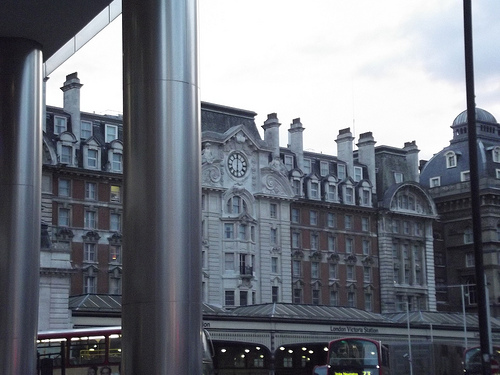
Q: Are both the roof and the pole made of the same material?
A: Yes, both the roof and the pole are made of metal.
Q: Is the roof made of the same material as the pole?
A: Yes, both the roof and the pole are made of metal.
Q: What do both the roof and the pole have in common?
A: The material, both the roof and the pole are metallic.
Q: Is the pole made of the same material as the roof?
A: Yes, both the pole and the roof are made of metal.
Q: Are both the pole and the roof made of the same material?
A: Yes, both the pole and the roof are made of metal.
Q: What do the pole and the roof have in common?
A: The material, both the pole and the roof are metallic.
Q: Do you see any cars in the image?
A: No, there are no cars.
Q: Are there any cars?
A: No, there are no cars.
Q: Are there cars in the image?
A: No, there are no cars.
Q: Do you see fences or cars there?
A: No, there are no cars or fences.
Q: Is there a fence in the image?
A: No, there are no fences.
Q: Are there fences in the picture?
A: No, there are no fences.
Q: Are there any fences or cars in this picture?
A: No, there are no fences or cars.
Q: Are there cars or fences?
A: No, there are no fences or cars.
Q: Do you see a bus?
A: Yes, there is a bus.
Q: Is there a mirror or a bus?
A: Yes, there is a bus.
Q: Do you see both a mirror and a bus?
A: Yes, there are both a bus and a mirror.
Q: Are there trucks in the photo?
A: No, there are no trucks.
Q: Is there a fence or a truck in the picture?
A: No, there are no trucks or fences.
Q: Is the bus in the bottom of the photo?
A: Yes, the bus is in the bottom of the image.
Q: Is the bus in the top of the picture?
A: No, the bus is in the bottom of the image.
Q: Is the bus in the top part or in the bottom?
A: The bus is in the bottom of the image.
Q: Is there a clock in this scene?
A: Yes, there is a clock.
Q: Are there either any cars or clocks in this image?
A: Yes, there is a clock.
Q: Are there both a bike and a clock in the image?
A: No, there is a clock but no bikes.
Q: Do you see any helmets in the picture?
A: No, there are no helmets.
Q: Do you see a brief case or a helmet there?
A: No, there are no helmets or briefcases.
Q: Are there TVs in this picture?
A: No, there are no tvs.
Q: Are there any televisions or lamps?
A: No, there are no televisions or lamps.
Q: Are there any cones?
A: No, there are no cones.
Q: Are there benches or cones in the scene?
A: No, there are no cones or benches.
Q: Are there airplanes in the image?
A: No, there are no airplanes.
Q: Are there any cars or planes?
A: No, there are no planes or cars.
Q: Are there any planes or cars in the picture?
A: No, there are no planes or cars.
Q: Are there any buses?
A: Yes, there is a bus.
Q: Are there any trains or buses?
A: Yes, there is a bus.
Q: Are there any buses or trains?
A: Yes, there is a bus.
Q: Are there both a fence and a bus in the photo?
A: No, there is a bus but no fences.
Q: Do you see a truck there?
A: No, there are no trucks.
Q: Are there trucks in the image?
A: No, there are no trucks.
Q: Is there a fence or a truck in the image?
A: No, there are no trucks or fences.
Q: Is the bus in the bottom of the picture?
A: Yes, the bus is in the bottom of the image.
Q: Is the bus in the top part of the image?
A: No, the bus is in the bottom of the image.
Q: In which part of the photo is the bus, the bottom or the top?
A: The bus is in the bottom of the image.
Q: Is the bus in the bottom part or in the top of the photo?
A: The bus is in the bottom of the image.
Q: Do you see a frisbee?
A: No, there are no frisbees.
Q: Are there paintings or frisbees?
A: No, there are no frisbees or paintings.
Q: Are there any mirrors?
A: Yes, there is a mirror.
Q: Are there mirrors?
A: Yes, there is a mirror.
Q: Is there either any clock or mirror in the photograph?
A: Yes, there is a mirror.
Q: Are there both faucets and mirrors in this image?
A: No, there is a mirror but no faucets.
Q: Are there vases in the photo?
A: No, there are no vases.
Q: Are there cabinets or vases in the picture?
A: No, there are no vases or cabinets.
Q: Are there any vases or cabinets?
A: No, there are no vases or cabinets.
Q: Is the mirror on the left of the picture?
A: Yes, the mirror is on the left of the image.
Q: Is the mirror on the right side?
A: No, the mirror is on the left of the image.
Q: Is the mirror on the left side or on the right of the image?
A: The mirror is on the left of the image.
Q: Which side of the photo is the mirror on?
A: The mirror is on the left of the image.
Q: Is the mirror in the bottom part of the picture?
A: Yes, the mirror is in the bottom of the image.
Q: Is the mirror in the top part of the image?
A: No, the mirror is in the bottom of the image.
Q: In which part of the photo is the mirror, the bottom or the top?
A: The mirror is in the bottom of the image.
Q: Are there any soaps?
A: No, there are no soaps.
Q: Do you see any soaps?
A: No, there are no soaps.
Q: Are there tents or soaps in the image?
A: No, there are no soaps or tents.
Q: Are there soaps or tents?
A: No, there are no soaps or tents.